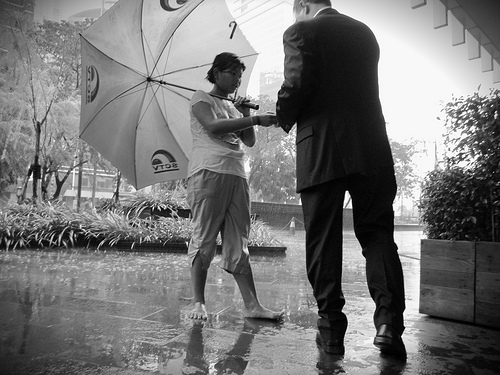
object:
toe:
[274, 311, 279, 321]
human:
[184, 50, 289, 321]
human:
[273, 0, 408, 356]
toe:
[196, 313, 203, 320]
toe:
[193, 312, 196, 318]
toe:
[187, 313, 194, 319]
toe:
[199, 311, 208, 321]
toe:
[188, 310, 198, 319]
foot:
[188, 303, 212, 321]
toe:
[197, 314, 202, 323]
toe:
[194, 311, 198, 321]